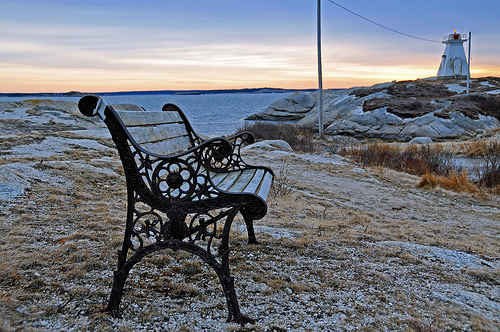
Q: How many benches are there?
A: One.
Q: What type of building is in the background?
A: A lighthouse.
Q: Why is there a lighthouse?
A: To protect boats.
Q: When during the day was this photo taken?
A: During sunset.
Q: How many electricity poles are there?
A: Two.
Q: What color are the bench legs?
A: Black.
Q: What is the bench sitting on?
A: Rocks and grass.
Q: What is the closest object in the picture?
A: The bench.